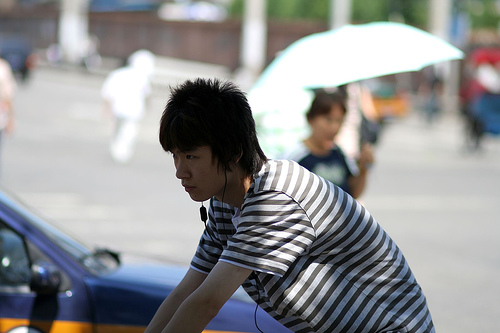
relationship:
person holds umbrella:
[278, 91, 375, 201] [244, 21, 466, 93]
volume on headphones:
[199, 204, 209, 223] [171, 86, 264, 332]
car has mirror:
[2, 195, 290, 331] [30, 261, 63, 295]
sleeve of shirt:
[216, 192, 315, 277] [191, 158, 436, 333]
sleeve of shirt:
[188, 197, 223, 275] [191, 158, 436, 333]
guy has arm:
[142, 79, 435, 331] [145, 198, 224, 324]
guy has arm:
[142, 79, 435, 331] [159, 190, 299, 330]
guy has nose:
[142, 79, 435, 331] [175, 158, 190, 180]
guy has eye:
[142, 79, 435, 331] [185, 154, 202, 160]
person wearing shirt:
[278, 91, 375, 201] [274, 140, 359, 194]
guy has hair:
[142, 79, 435, 331] [159, 77, 269, 176]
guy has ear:
[142, 79, 435, 331] [234, 142, 244, 164]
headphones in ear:
[171, 86, 264, 332] [234, 142, 244, 164]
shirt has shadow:
[191, 158, 436, 333] [304, 205, 431, 323]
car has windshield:
[2, 195, 290, 331] [2, 194, 107, 274]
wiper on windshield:
[79, 247, 123, 271] [2, 194, 107, 274]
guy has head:
[142, 79, 435, 331] [162, 80, 268, 202]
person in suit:
[100, 49, 160, 155] [98, 68, 150, 152]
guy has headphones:
[142, 79, 435, 331] [171, 86, 264, 332]